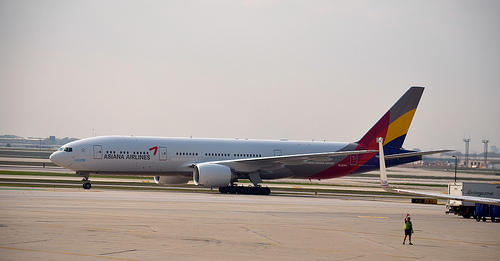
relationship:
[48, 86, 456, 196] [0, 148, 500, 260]
plane on runway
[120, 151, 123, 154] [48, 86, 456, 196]
window on plane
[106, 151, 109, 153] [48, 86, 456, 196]
window on plane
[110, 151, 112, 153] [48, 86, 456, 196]
window on plane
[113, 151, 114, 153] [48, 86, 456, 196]
window on plane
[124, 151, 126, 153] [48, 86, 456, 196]
window on plane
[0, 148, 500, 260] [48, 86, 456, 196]
runway under plane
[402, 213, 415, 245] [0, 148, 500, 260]
man on runway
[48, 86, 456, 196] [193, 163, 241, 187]
plane has engine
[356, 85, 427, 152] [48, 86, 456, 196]
tail on plane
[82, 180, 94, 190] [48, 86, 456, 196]
wheel on plane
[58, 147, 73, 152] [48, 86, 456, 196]
windshield of plane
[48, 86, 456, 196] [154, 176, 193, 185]
plane has engine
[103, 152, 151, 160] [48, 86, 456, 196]
name on plane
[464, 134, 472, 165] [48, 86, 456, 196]
tower behind plane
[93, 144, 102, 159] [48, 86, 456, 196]
door on plane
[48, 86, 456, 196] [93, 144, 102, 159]
plane has door